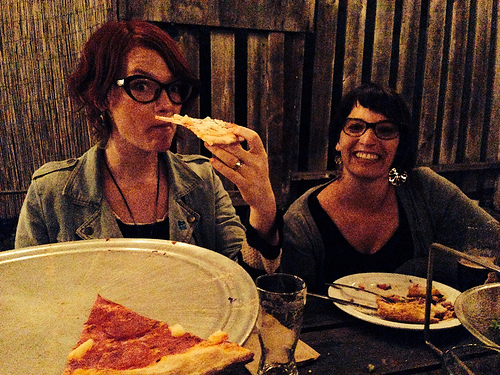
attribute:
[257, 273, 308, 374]
glass — empty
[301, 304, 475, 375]
table — wooden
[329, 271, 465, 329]
plate — white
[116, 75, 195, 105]
glasses — black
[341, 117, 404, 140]
glasses — dark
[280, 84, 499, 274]
woman — smiling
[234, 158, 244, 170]
ring — silver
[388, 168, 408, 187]
earring — large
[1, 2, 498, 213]
wall — wooden, thick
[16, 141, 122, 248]
jacket — green, denim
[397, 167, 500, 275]
sweater — grey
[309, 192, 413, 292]
shirt — black